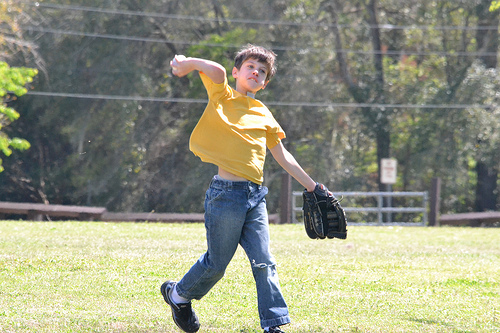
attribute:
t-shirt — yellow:
[187, 71, 288, 183]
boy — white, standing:
[157, 45, 349, 332]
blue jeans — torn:
[176, 174, 292, 327]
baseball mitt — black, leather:
[299, 186, 351, 245]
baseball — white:
[171, 51, 188, 67]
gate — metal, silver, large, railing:
[291, 186, 434, 230]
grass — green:
[2, 218, 498, 331]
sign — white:
[381, 158, 400, 185]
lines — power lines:
[2, 2, 500, 112]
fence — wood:
[2, 193, 498, 228]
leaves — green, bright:
[2, 57, 38, 162]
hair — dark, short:
[232, 44, 280, 84]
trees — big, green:
[1, 0, 499, 225]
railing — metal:
[291, 189, 430, 225]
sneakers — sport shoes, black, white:
[160, 278, 287, 332]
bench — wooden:
[3, 201, 106, 223]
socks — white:
[173, 284, 192, 304]